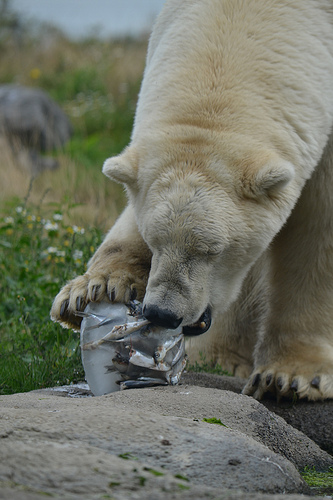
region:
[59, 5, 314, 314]
the bear is white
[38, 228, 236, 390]
the bear is biting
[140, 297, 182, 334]
the nose is black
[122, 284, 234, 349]
the mouth is open slightly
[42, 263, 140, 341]
the nails are dark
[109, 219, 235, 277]
the eyes are closed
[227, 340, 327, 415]
the paw is on the rock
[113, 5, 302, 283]
the bear is furry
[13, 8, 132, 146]
the background is blurry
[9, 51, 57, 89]
a yellow flower in the distance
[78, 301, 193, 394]
a frozen block of fish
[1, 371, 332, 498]
a rock under frozen fish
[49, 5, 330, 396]
a polar bear chewing on a frozen block of fish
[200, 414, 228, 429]
moss on a rock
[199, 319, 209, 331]
a tooth in a polar bear's mouth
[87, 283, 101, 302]
a black polar bear claw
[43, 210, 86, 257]
white flowers in the grass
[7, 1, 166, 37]
a pale blue sky behind a polar bear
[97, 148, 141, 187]
the ear of a polar bear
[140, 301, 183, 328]
the black nose of a polar bear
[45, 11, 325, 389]
The polar bear is white.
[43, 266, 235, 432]
The bear is eating fish.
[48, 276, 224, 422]
The fish are in a chunk of ice.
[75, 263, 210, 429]
The fish are white.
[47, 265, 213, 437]
The fish are grey.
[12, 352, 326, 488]
The ice is sitting on a rock.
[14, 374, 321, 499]
The rock is light grey.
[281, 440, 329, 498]
There is moss on the rock.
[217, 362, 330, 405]
His claw is on the rock.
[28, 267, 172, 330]
His claw is on the ice.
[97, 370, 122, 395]
part of a base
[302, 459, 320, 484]
part of a plant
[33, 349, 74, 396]
part of a grass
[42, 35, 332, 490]
A polar bear eating some small fish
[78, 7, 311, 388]
The bear is white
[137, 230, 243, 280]
The bear's eyes are closed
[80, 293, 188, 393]
Minnows trappe din a block of ice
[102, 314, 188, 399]
The fish are dead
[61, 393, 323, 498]
A rocky outcropping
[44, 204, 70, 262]
Small white flowers in the grass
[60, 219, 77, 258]
Small yellow flowers behind the bear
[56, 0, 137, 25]
A clear blue sky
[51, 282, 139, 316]
The bear's claws